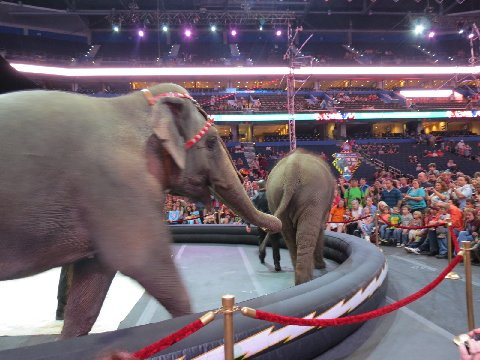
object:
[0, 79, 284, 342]
elephant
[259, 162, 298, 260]
tail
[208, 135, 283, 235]
trunk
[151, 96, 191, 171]
ear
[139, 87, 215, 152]
harness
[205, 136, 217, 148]
eye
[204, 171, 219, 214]
mouth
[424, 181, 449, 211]
people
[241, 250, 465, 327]
ropes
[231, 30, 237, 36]
lights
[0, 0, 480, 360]
stadium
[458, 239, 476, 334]
pole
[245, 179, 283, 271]
man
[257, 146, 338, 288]
elephant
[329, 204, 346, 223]
shirt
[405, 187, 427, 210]
shirt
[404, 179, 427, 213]
woman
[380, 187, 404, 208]
shirt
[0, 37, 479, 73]
bleachers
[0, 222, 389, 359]
circus ring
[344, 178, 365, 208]
man